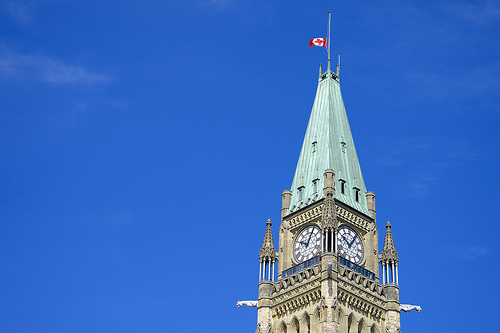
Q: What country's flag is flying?
A: Canada.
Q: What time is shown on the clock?
A: 10:05.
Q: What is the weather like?
A: Sunny.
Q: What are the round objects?
A: Clocks.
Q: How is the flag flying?
A: Half mast.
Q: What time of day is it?
A: Morning.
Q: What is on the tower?
A: Clock.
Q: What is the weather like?
A: Clear.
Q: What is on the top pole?
A: Flag.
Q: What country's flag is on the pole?
A: Canada.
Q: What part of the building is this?
A: Top.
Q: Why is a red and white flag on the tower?
A: To identify the country.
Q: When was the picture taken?
A: In the day.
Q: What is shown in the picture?
A: A clock tower.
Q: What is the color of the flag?
A: Red and white.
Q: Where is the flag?
A: On top of the roof.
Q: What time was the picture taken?
A: 10:05 am.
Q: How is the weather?
A: Clear.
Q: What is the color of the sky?
A: Blue.